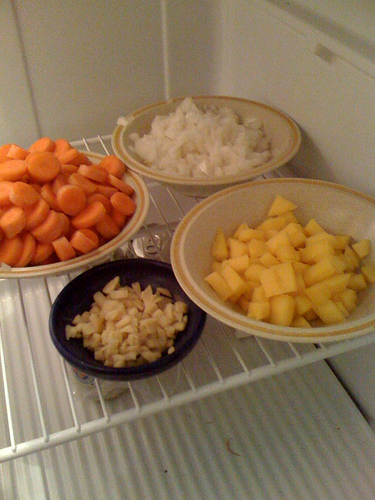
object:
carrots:
[0, 138, 136, 265]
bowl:
[0, 149, 152, 282]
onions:
[128, 99, 273, 180]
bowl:
[110, 89, 304, 189]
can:
[131, 224, 178, 259]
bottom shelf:
[0, 282, 375, 463]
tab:
[143, 233, 161, 251]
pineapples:
[206, 198, 375, 327]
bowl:
[49, 253, 210, 378]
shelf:
[1, 128, 373, 460]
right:
[168, 68, 373, 500]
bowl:
[171, 173, 374, 344]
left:
[0, 139, 209, 500]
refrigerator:
[0, 0, 375, 500]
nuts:
[64, 277, 188, 365]